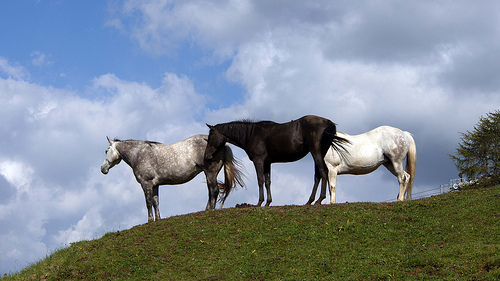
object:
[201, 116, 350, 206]
horse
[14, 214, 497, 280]
on a hill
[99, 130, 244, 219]
horse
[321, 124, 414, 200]
horse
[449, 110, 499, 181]
tree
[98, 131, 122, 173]
head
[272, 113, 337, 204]
back end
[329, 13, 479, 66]
clouds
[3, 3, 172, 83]
sky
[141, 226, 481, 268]
grass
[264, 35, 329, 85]
storm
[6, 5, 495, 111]
background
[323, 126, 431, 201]
back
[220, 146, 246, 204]
tail